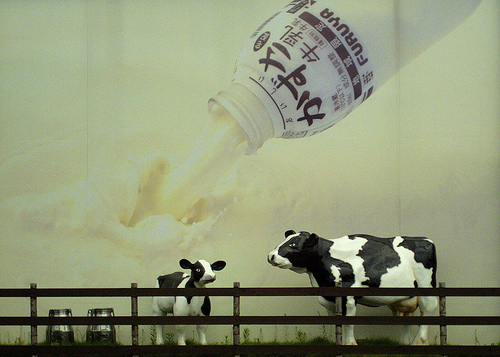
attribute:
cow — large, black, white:
[265, 225, 443, 350]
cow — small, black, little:
[150, 259, 228, 346]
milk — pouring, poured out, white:
[2, 108, 240, 257]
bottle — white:
[205, 1, 497, 156]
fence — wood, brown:
[2, 280, 498, 353]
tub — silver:
[82, 305, 119, 349]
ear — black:
[176, 256, 198, 271]